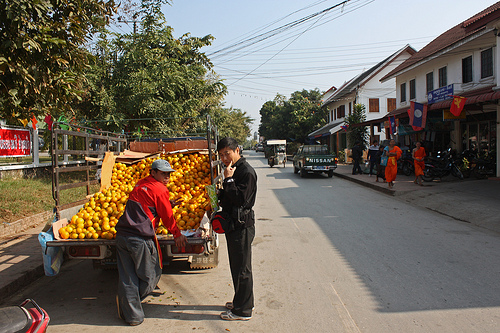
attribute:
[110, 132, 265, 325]
men — standing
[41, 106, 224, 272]
truck — nissan, small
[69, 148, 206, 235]
oranges — ripe, fruits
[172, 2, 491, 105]
sky — blue, clear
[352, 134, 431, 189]
people — walking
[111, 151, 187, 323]
man — in black, leaning, standing, wearing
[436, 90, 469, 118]
flag — hanging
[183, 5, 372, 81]
power lines — crossing, many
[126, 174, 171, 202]
top — red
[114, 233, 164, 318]
pants — gray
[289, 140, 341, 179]
truck — green, nissan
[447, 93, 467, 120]
sign — red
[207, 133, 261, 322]
man — standing, dressed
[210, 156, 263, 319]
outfit — black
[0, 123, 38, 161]
sign — red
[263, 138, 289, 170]
bicycle cart — white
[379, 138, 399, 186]
lady — walking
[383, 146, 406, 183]
dress — red